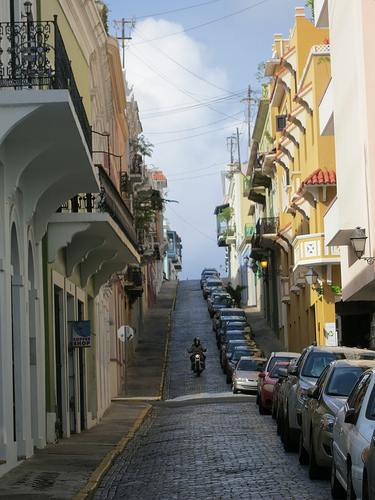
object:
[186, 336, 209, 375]
motorcycle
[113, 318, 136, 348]
sign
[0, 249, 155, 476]
shop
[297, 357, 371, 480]
cars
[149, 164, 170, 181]
roof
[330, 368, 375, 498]
car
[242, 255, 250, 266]
light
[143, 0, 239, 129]
sky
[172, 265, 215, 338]
road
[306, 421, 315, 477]
wheel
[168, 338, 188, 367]
surface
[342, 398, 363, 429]
mirror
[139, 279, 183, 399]
path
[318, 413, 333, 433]
headlight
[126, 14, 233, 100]
wires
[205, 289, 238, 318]
vehicles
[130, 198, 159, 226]
flower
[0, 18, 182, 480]
building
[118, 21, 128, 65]
pole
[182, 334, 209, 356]
man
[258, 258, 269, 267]
bulb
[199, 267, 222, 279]
vehicle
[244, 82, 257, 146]
post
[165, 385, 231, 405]
lump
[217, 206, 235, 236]
tree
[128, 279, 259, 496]
street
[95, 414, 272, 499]
cobbletsones